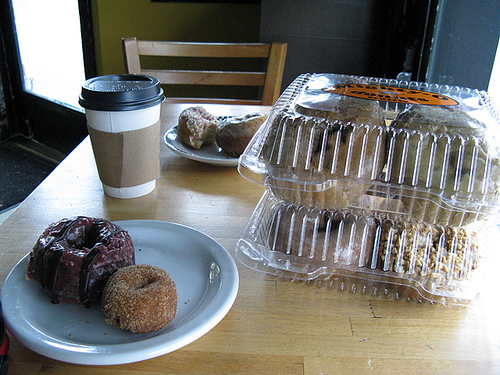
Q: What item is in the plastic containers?
A: Doughnuts.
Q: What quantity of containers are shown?
A: Two.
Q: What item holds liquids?
A: A cup.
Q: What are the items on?
A: The table.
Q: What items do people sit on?
A: A chair.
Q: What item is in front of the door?
A: A rug.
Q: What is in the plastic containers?
A: Doughnuts.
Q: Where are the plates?
A: On the table.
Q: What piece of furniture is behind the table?
A: A wooden chair.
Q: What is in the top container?
A: Doughnuts.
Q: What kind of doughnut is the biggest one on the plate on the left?
A: Chocolate.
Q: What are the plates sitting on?
A: A wooden table.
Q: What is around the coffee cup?
A: A cardboard wrapper.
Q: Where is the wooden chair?
A: Behind the table.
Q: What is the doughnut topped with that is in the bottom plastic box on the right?
A: Nuts.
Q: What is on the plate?
A: Doughnuts.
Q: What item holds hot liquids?
A: Coffee cup.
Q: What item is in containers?
A: Doughnuts.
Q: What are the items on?
A: A table.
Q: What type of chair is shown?
A: A wooden chair.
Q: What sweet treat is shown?
A: Doughnuts.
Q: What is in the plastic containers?
A: Doughuts.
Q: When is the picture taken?
A: Daytime.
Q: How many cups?
A: One.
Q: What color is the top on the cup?
A: Black.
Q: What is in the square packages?
A: Donuts.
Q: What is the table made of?
A: Wood.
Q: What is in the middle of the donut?
A: A hole.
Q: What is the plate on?
A: A table.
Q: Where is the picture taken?
A: At a restaurant.